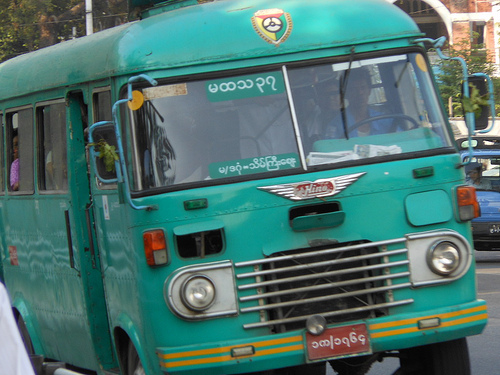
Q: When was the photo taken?
A: During the day.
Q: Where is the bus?
A: On the road.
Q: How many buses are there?
A: One.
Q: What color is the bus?
A: Green.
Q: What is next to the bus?
A: A building.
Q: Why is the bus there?
A: To transport people.